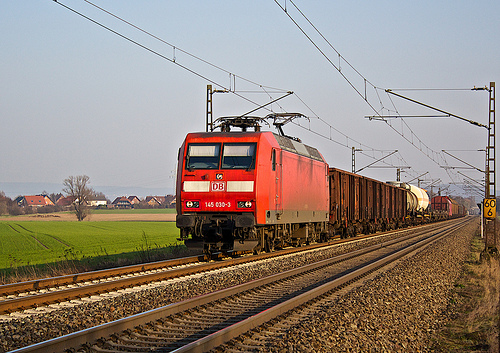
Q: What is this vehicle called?
A: Train.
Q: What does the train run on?
A: Tracks.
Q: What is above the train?
A: Electrical lines.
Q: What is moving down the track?
A: Train.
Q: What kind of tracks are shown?
A: Train.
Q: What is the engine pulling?
A: Train cars.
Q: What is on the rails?
A: Train.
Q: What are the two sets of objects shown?
A: Railroads.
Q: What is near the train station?
A: Homes.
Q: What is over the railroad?
A: Wires.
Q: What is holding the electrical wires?
A: Poles.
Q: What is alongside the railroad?
A: Gravel.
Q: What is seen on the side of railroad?
A: Paddy Field.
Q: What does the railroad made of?
A: Iron metal.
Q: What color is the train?
A: Red.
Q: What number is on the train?
A: 08.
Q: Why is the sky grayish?
A: Its getting dark.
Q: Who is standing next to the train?
A: Nobody.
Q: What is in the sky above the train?
A: Wires.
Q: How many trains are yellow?
A: None.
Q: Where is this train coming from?
A: Right.